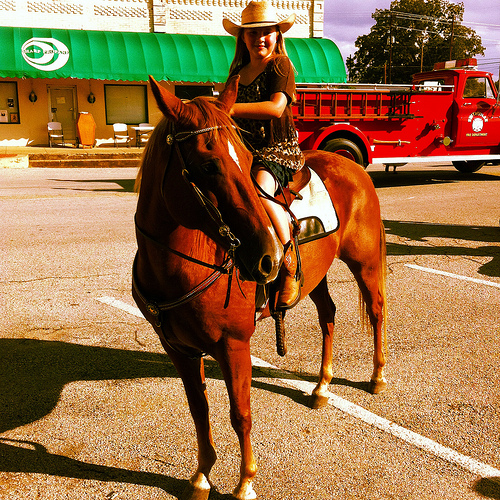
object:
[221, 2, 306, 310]
girl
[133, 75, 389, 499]
horse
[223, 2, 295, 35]
hat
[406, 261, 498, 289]
line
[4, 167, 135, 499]
ground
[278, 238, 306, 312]
boot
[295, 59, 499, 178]
firetruck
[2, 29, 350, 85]
awning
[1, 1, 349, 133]
building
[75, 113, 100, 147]
coffin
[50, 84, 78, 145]
door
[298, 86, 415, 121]
ladder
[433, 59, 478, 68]
light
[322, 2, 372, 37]
sky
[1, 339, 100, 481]
shadow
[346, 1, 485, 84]
tree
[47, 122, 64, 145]
chair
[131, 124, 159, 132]
table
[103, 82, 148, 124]
window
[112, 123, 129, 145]
chair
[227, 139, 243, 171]
spot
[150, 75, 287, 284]
head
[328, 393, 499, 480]
line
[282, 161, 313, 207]
saddle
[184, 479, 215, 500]
hoof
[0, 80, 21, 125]
window